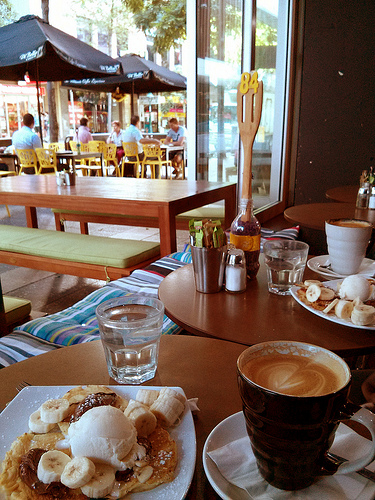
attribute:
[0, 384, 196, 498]
plate — white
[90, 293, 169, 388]
glass — clear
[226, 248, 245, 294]
salt shaker — glass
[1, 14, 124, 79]
umbrella — black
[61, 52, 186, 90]
umbrella — black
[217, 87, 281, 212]
spatula — tall, wood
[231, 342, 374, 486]
coffee mug — dark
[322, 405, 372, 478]
handle — light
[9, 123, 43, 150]
shirt — blue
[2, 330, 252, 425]
plate — large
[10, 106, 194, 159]
people — sitting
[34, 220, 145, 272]
cushion — light green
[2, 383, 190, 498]
dessert — sweet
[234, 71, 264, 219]
spoon — wooden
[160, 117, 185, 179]
person — sitting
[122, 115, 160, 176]
person — sitting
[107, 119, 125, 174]
person — sitting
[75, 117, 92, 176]
person — sitting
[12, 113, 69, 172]
person — sitting